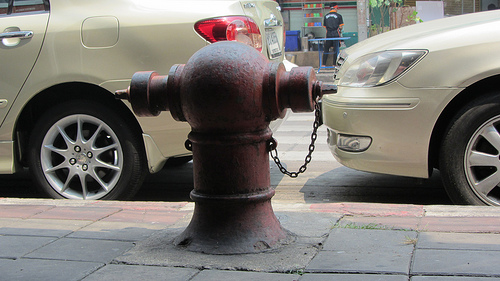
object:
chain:
[267, 102, 326, 179]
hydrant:
[113, 40, 340, 257]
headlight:
[338, 48, 430, 89]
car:
[323, 8, 499, 207]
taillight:
[192, 14, 263, 55]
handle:
[0, 29, 35, 40]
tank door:
[79, 15, 119, 49]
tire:
[25, 96, 145, 201]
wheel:
[40, 113, 123, 201]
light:
[335, 131, 373, 153]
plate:
[265, 31, 283, 60]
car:
[0, 1, 287, 202]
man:
[322, 7, 344, 68]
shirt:
[323, 12, 344, 33]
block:
[317, 70, 333, 81]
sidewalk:
[4, 195, 499, 281]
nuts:
[74, 146, 81, 151]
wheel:
[463, 115, 499, 206]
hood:
[335, 9, 499, 89]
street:
[269, 66, 426, 203]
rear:
[235, 1, 290, 135]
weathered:
[140, 36, 314, 236]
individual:
[19, 237, 134, 263]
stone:
[79, 262, 200, 281]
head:
[319, 31, 384, 175]